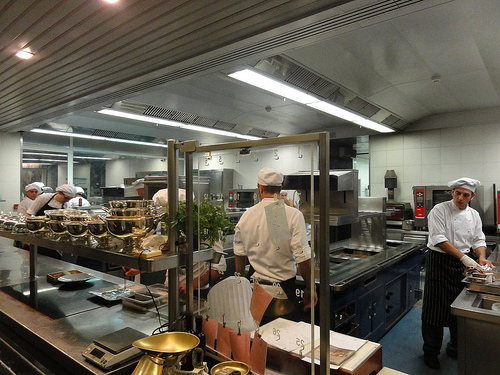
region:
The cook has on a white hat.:
[423, 170, 488, 210]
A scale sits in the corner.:
[80, 325, 152, 374]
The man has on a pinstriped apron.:
[422, 243, 480, 340]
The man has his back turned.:
[233, 173, 318, 328]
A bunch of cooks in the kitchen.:
[28, 167, 128, 217]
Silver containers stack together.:
[26, 180, 174, 249]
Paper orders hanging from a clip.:
[189, 301, 284, 373]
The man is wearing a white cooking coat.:
[241, 192, 345, 293]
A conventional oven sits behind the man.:
[396, 183, 498, 230]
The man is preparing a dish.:
[426, 242, 497, 294]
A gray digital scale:
[82, 323, 148, 370]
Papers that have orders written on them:
[197, 199, 292, 374]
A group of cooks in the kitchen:
[15, 169, 492, 357]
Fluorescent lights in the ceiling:
[17, 65, 395, 164]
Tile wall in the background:
[57, 122, 498, 214]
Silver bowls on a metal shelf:
[25, 201, 167, 247]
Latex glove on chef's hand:
[460, 253, 485, 272]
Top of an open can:
[206, 360, 250, 374]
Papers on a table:
[252, 316, 367, 371]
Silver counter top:
[1, 245, 175, 372]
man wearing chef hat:
[421, 176, 493, 367]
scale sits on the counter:
[83, 322, 146, 367]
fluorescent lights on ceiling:
[228, 70, 397, 135]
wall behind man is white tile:
[371, 125, 499, 217]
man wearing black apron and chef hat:
[28, 184, 77, 217]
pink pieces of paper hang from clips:
[247, 282, 269, 322]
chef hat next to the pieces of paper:
[202, 272, 257, 332]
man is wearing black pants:
[420, 200, 486, 368]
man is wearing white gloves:
[457, 252, 492, 269]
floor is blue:
[374, 271, 481, 373]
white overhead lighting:
[235, 58, 357, 113]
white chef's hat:
[428, 174, 483, 192]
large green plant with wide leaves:
[166, 195, 223, 240]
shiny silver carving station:
[10, 282, 127, 342]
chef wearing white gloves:
[456, 246, 485, 271]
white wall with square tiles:
[394, 134, 476, 168]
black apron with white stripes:
[418, 244, 480, 341]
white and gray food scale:
[81, 328, 157, 374]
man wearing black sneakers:
[404, 338, 459, 365]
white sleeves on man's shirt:
[413, 227, 455, 253]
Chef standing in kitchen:
[247, 167, 311, 280]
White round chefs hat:
[445, 176, 486, 189]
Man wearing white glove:
[462, 255, 475, 267]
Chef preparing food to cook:
[420, 175, 492, 372]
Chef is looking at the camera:
[15, 185, 42, 208]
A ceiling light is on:
[11, 49, 37, 62]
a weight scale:
[81, 322, 152, 364]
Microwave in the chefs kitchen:
[226, 189, 256, 208]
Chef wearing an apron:
[30, 181, 77, 210]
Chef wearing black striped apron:
[428, 252, 465, 333]